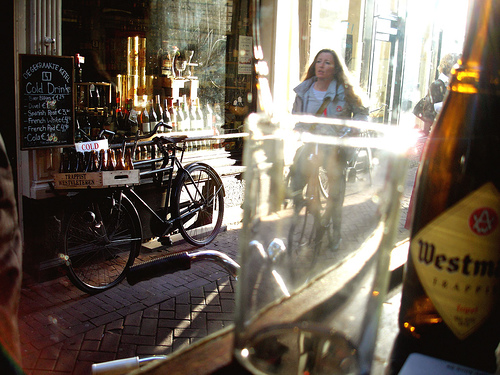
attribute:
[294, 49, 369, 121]
woman — standing, riding, looking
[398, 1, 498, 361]
bottle — brown, glass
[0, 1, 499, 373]
bar — room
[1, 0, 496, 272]
building — large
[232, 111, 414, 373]
glass — large, cup, clear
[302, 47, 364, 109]
hair — long, curly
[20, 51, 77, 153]
sign — chalk, white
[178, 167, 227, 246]
wheel — black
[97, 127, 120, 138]
handle — black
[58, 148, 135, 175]
bottle — rowed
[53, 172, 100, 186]
logo — brand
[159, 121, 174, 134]
handle — white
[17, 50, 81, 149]
chalkboard — menu, black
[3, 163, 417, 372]
road — brick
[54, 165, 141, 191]
crate — wooden